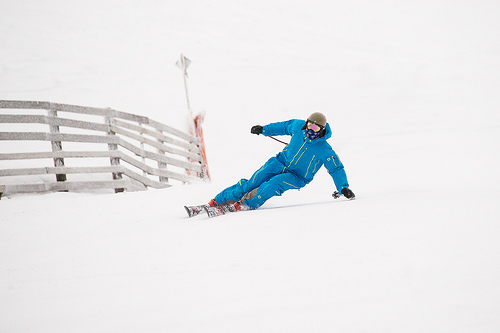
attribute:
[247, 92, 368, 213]
man — skiing, cold, whiet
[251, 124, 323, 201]
suit — blue, black, dark, brow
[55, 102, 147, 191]
fence — white, wood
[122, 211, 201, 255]
snow — coming down, falling, white, fresh